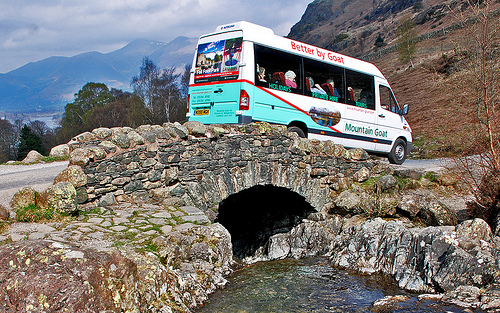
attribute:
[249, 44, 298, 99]
window van — side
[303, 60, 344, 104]
window — side